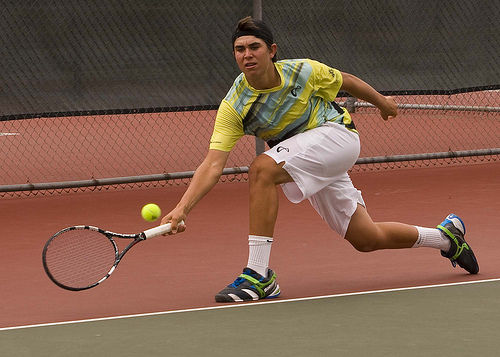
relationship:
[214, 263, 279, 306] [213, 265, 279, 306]
sneakers on foot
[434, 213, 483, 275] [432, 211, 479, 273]
sneakers on foot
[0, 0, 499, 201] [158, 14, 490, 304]
fence behind man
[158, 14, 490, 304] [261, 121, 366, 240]
man wears shorts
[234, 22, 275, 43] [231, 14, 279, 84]
headband on head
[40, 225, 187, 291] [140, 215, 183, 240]
racket has white handle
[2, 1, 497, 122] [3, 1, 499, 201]
tarp on fence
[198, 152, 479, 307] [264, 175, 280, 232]
leg has muscle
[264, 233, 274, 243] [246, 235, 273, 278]
nike brand on sock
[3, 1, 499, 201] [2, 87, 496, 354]
fence around tennis court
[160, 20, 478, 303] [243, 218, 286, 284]
man wearing sock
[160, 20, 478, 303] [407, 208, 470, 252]
man wearing sock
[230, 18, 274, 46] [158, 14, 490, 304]
cap on man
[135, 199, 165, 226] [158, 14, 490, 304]
tennis ball hit by man